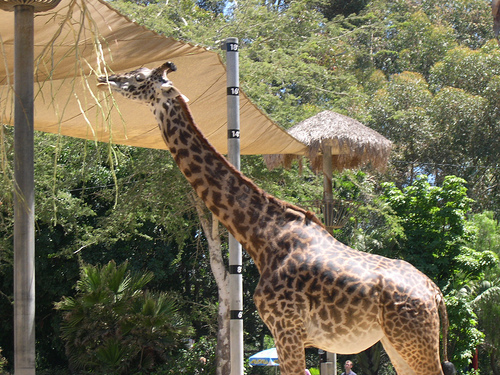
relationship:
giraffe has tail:
[95, 58, 452, 370] [439, 297, 453, 366]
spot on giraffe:
[331, 283, 350, 311] [95, 58, 452, 370]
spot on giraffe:
[322, 298, 352, 328] [95, 58, 452, 370]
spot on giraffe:
[397, 308, 408, 324] [95, 58, 452, 370]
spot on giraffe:
[345, 313, 368, 333] [95, 58, 452, 370]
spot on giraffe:
[265, 296, 288, 324] [95, 58, 452, 370]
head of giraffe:
[93, 57, 169, 104] [95, 58, 452, 370]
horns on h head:
[154, 61, 174, 83] [93, 62, 170, 104]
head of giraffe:
[93, 62, 170, 104] [95, 58, 452, 370]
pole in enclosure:
[10, 18, 42, 369] [19, 18, 491, 365]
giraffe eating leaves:
[95, 58, 452, 370] [84, 53, 113, 115]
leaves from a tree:
[84, 53, 113, 115] [33, 15, 125, 262]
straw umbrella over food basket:
[268, 112, 395, 169] [307, 193, 355, 233]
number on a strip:
[228, 127, 242, 139] [222, 130, 243, 140]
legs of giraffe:
[377, 290, 442, 374] [95, 58, 452, 370]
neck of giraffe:
[161, 90, 307, 259] [95, 58, 452, 370]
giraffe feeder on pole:
[0, 3, 115, 136] [0, 76, 84, 260]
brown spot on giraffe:
[269, 207, 309, 257] [95, 58, 452, 370]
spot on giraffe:
[163, 116, 178, 136] [95, 58, 452, 370]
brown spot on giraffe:
[187, 139, 204, 163] [134, 73, 465, 370]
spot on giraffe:
[190, 152, 204, 164] [95, 58, 452, 370]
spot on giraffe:
[185, 124, 193, 134] [95, 58, 452, 370]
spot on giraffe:
[350, 295, 360, 307] [95, 58, 452, 370]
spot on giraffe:
[383, 290, 393, 300] [95, 58, 452, 370]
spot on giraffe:
[308, 312, 318, 332] [95, 58, 452, 370]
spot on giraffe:
[223, 189, 238, 210] [95, 58, 452, 370]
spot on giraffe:
[244, 221, 268, 251] [115, 58, 480, 325]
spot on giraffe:
[285, 259, 297, 276] [95, 58, 452, 370]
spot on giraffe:
[282, 254, 299, 276] [95, 58, 452, 370]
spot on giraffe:
[204, 181, 229, 213] [80, 56, 472, 373]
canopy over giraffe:
[3, 7, 320, 181] [95, 58, 452, 370]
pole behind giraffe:
[201, 20, 261, 371] [95, 58, 452, 370]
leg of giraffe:
[269, 337, 322, 371] [95, 58, 452, 370]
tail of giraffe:
[433, 290, 461, 372] [95, 58, 452, 370]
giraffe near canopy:
[95, 58, 452, 370] [3, 7, 320, 181]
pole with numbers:
[221, 54, 248, 371] [223, 36, 246, 326]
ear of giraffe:
[145, 49, 189, 81] [78, 43, 428, 371]